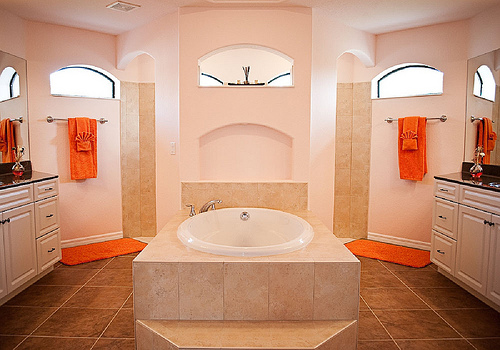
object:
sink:
[486, 181, 499, 187]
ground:
[0, 230, 499, 350]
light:
[225, 65, 265, 86]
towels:
[395, 116, 427, 182]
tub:
[175, 206, 315, 257]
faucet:
[183, 199, 224, 217]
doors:
[331, 49, 377, 242]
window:
[268, 72, 291, 88]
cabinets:
[483, 213, 499, 307]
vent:
[103, 0, 140, 15]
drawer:
[433, 178, 459, 203]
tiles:
[32, 307, 118, 338]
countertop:
[433, 170, 499, 192]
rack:
[382, 114, 448, 123]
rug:
[342, 238, 432, 269]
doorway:
[329, 47, 395, 250]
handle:
[437, 188, 451, 193]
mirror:
[462, 48, 500, 165]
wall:
[366, 20, 468, 252]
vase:
[469, 145, 485, 179]